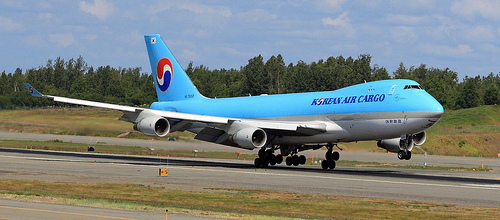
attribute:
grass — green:
[0, 102, 498, 217]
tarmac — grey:
[2, 130, 498, 216]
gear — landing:
[215, 128, 353, 218]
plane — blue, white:
[22, 30, 451, 174]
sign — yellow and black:
[159, 167, 168, 177]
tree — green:
[64, 55, 94, 100]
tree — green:
[104, 68, 125, 108]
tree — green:
[119, 65, 139, 101]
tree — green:
[136, 67, 154, 103]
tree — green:
[0, 67, 18, 97]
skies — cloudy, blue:
[168, 1, 373, 43]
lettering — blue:
[310, 92, 385, 104]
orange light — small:
[155, 165, 172, 177]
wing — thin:
[29, 88, 307, 153]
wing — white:
[43, 60, 264, 176]